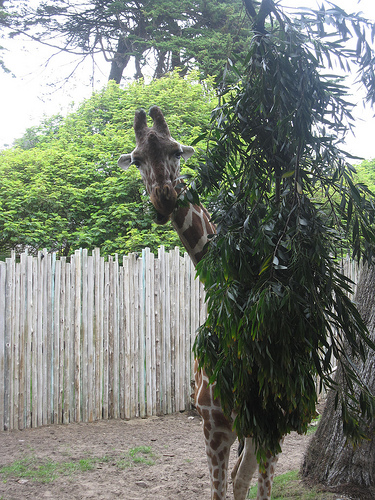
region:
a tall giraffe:
[108, 84, 356, 484]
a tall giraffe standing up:
[68, 86, 357, 426]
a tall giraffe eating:
[107, 55, 372, 374]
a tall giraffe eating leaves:
[48, 50, 373, 429]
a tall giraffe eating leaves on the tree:
[57, 68, 321, 343]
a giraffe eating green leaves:
[115, 79, 305, 383]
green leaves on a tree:
[191, 144, 338, 410]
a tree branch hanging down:
[106, 6, 334, 307]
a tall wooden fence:
[24, 208, 364, 461]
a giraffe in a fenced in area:
[41, 181, 372, 463]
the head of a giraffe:
[109, 104, 216, 234]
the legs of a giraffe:
[180, 406, 295, 491]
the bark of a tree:
[321, 394, 370, 484]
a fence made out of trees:
[25, 282, 165, 410]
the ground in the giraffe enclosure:
[39, 442, 145, 489]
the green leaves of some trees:
[18, 144, 117, 238]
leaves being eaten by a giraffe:
[136, 179, 236, 227]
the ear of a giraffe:
[108, 150, 150, 174]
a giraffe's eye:
[172, 145, 185, 160]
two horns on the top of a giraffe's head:
[129, 105, 173, 141]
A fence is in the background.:
[0, 242, 164, 389]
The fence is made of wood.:
[1, 245, 158, 365]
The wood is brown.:
[1, 239, 144, 344]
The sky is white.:
[2, 82, 32, 119]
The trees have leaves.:
[1, 103, 112, 245]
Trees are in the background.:
[0, 100, 108, 240]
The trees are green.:
[1, 106, 108, 238]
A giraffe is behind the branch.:
[100, 99, 333, 498]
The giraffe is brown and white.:
[105, 97, 318, 496]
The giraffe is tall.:
[108, 92, 306, 499]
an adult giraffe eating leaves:
[93, 106, 241, 243]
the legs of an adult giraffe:
[192, 395, 279, 497]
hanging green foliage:
[198, 355, 323, 463]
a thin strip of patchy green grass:
[2, 450, 175, 490]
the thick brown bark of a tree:
[327, 413, 373, 476]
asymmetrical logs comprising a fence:
[15, 257, 165, 412]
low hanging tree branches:
[210, 80, 365, 434]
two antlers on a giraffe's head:
[120, 101, 182, 142]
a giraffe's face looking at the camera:
[100, 100, 222, 260]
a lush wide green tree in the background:
[9, 88, 155, 286]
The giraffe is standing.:
[110, 103, 290, 498]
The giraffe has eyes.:
[84, 102, 227, 261]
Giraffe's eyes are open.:
[103, 96, 235, 249]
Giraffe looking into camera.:
[104, 105, 212, 240]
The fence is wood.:
[0, 238, 351, 436]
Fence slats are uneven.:
[1, 244, 331, 428]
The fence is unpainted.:
[0, 243, 356, 439]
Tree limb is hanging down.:
[177, 1, 370, 469]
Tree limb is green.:
[167, 1, 374, 479]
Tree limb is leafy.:
[162, 0, 374, 476]